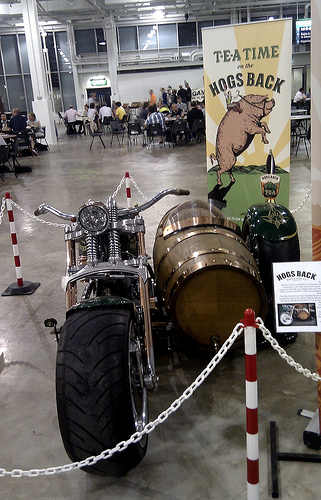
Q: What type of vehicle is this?
A: Motorcycle.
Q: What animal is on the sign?
A: Hog.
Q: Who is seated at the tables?
A: Many people.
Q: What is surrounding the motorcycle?
A: Chains.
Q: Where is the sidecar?
A: Left side of the bike.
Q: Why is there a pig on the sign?
A: Some motorcycles are called hogs.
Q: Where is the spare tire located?
A: Attached to the outside of the sidecar.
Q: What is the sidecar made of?
A: Wood and metal.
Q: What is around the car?
A: A plastic chain.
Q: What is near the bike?
A: A sign with a pig.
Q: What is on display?
A: A motorcycle with a sidecar.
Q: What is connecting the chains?
A: A striped pole.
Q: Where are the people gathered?
A: In the back of the building.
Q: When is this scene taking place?
A: Night time.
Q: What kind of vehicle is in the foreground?
A: Motorcycle.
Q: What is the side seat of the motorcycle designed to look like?
A: Barrel.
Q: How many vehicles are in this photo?
A: One.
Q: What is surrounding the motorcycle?
A: White chain fence.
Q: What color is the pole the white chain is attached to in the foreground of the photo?
A: Red and white.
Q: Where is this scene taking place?
A: Inside a convention center.